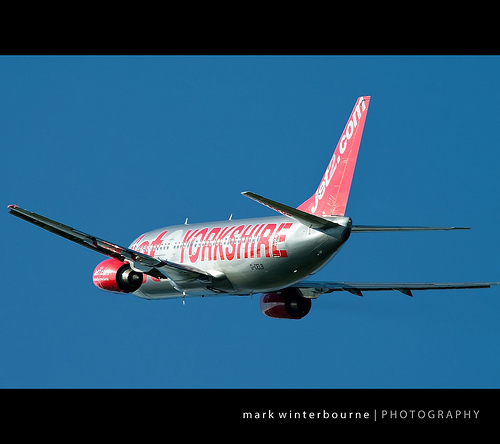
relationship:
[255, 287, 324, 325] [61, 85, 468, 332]
engine on plane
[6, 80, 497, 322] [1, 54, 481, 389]
airplane flying on skies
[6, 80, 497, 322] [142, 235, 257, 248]
airplane has windows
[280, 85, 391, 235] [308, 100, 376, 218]
red tail has a letters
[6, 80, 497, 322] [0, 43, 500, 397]
airplane driving in air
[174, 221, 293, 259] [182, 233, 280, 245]
name written in red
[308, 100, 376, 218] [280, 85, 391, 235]
letters are written on red tail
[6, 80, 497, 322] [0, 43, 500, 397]
airplane flying in air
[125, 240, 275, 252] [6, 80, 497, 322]
windows are fixed to sides of airplane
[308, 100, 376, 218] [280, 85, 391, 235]
letters on red tail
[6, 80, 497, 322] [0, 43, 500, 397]
airplane in air